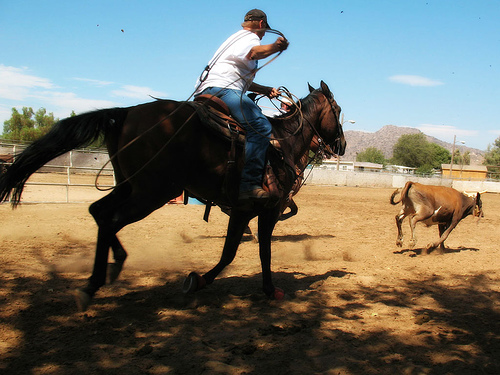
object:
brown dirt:
[0, 172, 500, 375]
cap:
[245, 9, 273, 30]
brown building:
[441, 164, 487, 181]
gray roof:
[440, 163, 488, 172]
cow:
[390, 181, 484, 256]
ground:
[0, 171, 500, 375]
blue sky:
[0, 0, 500, 151]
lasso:
[94, 27, 304, 191]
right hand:
[272, 37, 289, 52]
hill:
[324, 124, 500, 162]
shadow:
[0, 234, 500, 375]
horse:
[0, 80, 347, 309]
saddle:
[180, 93, 281, 149]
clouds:
[0, 63, 163, 121]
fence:
[0, 141, 500, 194]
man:
[194, 8, 286, 201]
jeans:
[193, 86, 274, 189]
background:
[0, 124, 499, 373]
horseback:
[150, 95, 274, 148]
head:
[242, 9, 268, 41]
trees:
[356, 132, 471, 178]